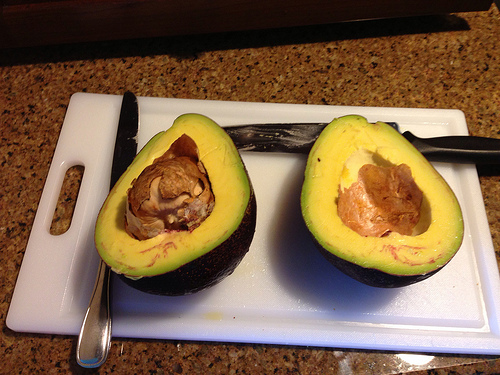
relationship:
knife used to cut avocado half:
[177, 108, 499, 171] [93, 112, 257, 297]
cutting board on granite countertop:
[3, 89, 496, 357] [2, 26, 499, 374]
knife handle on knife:
[73, 241, 113, 368] [65, 272, 114, 372]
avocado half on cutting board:
[94, 113, 255, 296] [3, 89, 496, 357]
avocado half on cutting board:
[299, 115, 465, 288] [3, 89, 496, 357]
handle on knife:
[402, 127, 499, 166] [178, 112, 498, 159]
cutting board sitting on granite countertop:
[3, 89, 496, 357] [2, 26, 499, 374]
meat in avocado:
[122, 128, 219, 231] [92, 110, 258, 296]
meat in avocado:
[331, 157, 427, 240] [293, 110, 465, 288]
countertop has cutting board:
[7, 10, 497, 372] [3, 89, 496, 357]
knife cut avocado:
[220, 121, 498, 164] [98, 91, 483, 303]